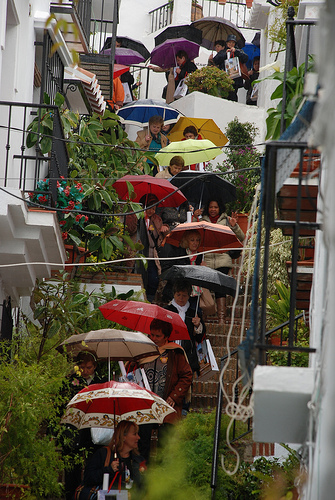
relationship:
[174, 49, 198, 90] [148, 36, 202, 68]
man holds umbrella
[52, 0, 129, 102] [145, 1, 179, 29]
balcony has railing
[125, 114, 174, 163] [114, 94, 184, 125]
woman holds umbrella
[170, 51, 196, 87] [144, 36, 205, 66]
man holding umbrella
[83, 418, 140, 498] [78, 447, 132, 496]
people holding purse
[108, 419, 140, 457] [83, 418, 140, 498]
hair of people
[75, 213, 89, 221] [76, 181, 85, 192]
blossom of flower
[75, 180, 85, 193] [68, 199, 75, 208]
blossom of flower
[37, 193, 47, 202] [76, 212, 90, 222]
blossom of flower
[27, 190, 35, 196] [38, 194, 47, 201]
blossom of flower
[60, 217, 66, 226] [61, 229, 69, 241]
blossom of flower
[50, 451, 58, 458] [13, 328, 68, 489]
leaf of tree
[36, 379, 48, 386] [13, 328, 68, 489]
leaf of tree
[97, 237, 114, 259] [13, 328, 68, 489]
leaf of tree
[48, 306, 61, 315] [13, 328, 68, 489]
leaf of tree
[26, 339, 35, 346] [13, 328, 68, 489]
leaf of tree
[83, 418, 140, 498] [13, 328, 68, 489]
people next to tree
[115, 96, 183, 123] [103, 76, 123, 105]
umbrella next to man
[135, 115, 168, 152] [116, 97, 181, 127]
blonde woman with a umbrella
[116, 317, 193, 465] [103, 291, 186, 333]
person with a umbrellas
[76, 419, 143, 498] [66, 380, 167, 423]
woman with a umbrellas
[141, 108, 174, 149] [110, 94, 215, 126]
woman with a umbrellas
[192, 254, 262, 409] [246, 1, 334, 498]
stairs between building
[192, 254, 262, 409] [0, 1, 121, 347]
stairs between building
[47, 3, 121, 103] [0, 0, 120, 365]
balcony on building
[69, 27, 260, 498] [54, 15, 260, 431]
people holding umbrellas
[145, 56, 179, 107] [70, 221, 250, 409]
person going down stairs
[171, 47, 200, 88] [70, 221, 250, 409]
person going down stairs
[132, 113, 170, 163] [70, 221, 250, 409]
person going down stairs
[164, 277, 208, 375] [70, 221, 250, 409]
person going down stairs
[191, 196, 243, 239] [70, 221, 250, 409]
person going down stairs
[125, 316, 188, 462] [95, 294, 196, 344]
woman holding umbrella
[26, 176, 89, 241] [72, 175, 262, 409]
flowers on side of stairs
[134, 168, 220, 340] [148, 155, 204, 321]
people with umbrellas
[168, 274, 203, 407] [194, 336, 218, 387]
lady with a shopping bag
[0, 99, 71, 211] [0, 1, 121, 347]
balcony on building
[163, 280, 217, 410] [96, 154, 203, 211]
lady carrying a umbrella